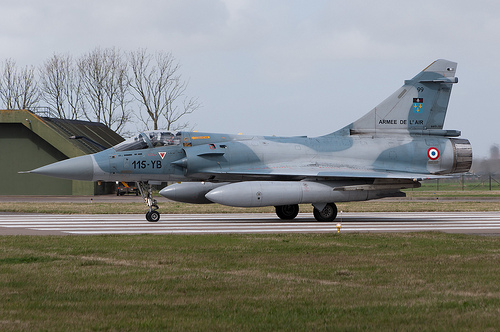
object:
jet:
[18, 59, 472, 222]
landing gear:
[139, 180, 161, 222]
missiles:
[205, 181, 419, 208]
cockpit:
[111, 130, 183, 152]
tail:
[323, 60, 457, 134]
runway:
[0, 210, 500, 234]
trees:
[0, 61, 50, 120]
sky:
[0, 0, 500, 162]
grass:
[1, 236, 247, 331]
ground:
[0, 182, 500, 331]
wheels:
[146, 211, 160, 222]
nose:
[16, 165, 49, 176]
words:
[379, 119, 424, 125]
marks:
[0, 210, 499, 232]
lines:
[0, 210, 499, 237]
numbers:
[132, 160, 147, 169]